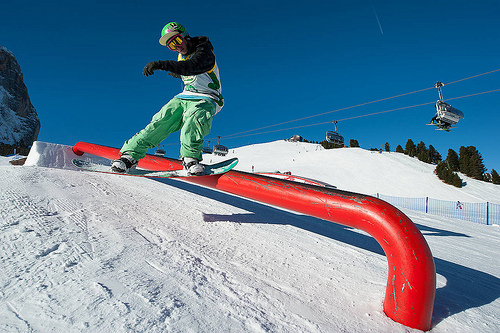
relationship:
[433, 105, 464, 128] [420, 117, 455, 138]
people wearing skis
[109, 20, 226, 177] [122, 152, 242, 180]
snowboarder on top of snowboard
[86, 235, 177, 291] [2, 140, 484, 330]
snow covering ski slope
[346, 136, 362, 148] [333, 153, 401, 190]
tree on snowy hill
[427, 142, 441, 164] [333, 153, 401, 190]
tree on snowy hill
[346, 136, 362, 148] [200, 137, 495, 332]
tree on hill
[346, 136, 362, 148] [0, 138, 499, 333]
tree on snowy hill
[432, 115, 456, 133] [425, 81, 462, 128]
people sitting in lift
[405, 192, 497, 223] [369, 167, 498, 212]
net surrounding ski slope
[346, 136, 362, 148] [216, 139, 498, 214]
tree on hill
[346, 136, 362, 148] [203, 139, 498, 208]
tree on hill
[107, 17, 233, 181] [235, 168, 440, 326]
snowboarder on rail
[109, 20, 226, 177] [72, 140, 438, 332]
snowboarder on rail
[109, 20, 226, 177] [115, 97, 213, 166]
snowboarder wearing green pants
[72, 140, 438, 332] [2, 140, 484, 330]
rail to ski slope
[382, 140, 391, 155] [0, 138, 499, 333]
tree on snowy hill